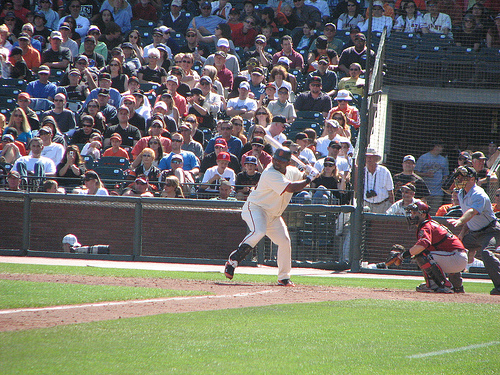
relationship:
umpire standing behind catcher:
[445, 162, 499, 295] [385, 198, 474, 299]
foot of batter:
[221, 252, 239, 280] [220, 134, 322, 291]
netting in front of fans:
[397, 61, 485, 130] [1, 1, 231, 173]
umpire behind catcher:
[445, 162, 499, 295] [385, 198, 474, 299]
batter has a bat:
[220, 134, 322, 291] [261, 133, 307, 169]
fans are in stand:
[1, 1, 231, 173] [9, 7, 393, 211]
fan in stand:
[159, 129, 198, 167] [9, 7, 393, 211]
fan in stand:
[104, 102, 146, 146] [7, 8, 404, 236]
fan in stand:
[71, 113, 100, 141] [7, 7, 391, 259]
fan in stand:
[87, 72, 120, 104] [7, 7, 391, 259]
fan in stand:
[156, 71, 187, 113] [7, 8, 404, 236]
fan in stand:
[227, 81, 261, 115] [9, 7, 393, 211]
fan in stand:
[263, 84, 301, 124] [9, 7, 393, 211]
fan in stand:
[295, 72, 333, 112] [9, 7, 393, 211]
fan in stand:
[267, 65, 294, 99] [9, 7, 393, 211]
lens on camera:
[95, 245, 108, 256] [69, 242, 114, 257]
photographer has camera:
[58, 226, 116, 263] [69, 242, 114, 257]